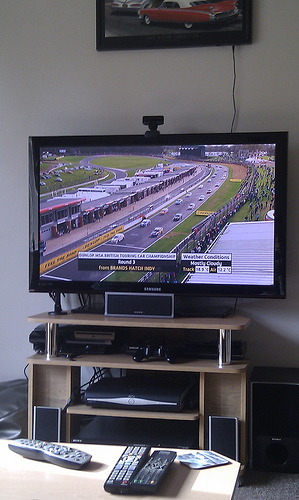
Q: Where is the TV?
A: TV stand.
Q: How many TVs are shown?
A: One.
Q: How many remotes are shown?
A: Three.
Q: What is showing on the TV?
A: Race cars.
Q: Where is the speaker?
A: Floor.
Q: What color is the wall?
A: White.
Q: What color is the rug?
A: Tan.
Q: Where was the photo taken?
A: In a living room.